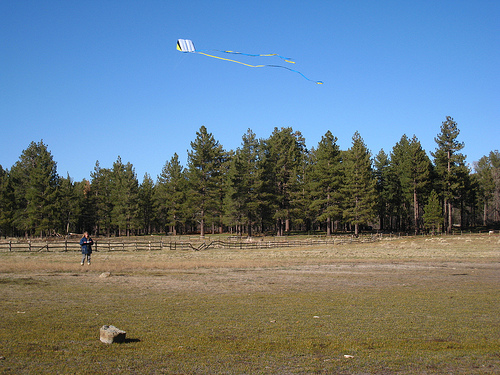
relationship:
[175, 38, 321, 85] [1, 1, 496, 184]
kite in sky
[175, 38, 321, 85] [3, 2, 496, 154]
kite in sky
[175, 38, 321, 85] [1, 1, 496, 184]
kite across sky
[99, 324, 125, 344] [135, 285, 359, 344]
tree stump in field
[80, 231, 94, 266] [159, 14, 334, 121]
girl with kite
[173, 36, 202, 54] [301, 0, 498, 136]
kite in sky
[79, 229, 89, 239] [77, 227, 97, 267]
hair on woman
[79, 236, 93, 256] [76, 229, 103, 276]
blue coat on woman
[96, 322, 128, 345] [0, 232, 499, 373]
stone in field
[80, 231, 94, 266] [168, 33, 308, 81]
girl with kite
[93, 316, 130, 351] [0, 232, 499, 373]
tree stump in field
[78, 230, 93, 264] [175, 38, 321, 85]
girl flies kite